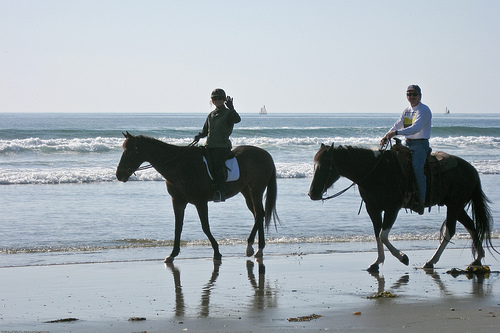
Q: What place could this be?
A: It is a beach.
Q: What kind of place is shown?
A: It is a beach.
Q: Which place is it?
A: It is a beach.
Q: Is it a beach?
A: Yes, it is a beach.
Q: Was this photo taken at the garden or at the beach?
A: It was taken at the beach.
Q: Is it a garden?
A: No, it is a beach.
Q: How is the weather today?
A: It is clear.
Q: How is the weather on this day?
A: It is clear.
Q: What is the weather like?
A: It is clear.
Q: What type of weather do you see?
A: It is clear.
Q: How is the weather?
A: It is clear.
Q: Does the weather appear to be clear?
A: Yes, it is clear.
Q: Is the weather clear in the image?
A: Yes, it is clear.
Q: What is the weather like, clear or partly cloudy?
A: It is clear.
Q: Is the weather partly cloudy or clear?
A: It is clear.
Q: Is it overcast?
A: No, it is clear.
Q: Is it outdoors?
A: Yes, it is outdoors.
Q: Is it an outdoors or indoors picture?
A: It is outdoors.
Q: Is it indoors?
A: No, it is outdoors.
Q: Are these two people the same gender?
A: No, they are both male and female.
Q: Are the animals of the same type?
A: Yes, all the animals are horses.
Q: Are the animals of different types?
A: No, all the animals are horses.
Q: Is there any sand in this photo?
A: Yes, there is sand.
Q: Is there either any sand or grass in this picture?
A: Yes, there is sand.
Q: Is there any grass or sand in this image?
A: Yes, there is sand.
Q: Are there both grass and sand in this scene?
A: No, there is sand but no grass.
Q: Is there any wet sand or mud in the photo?
A: Yes, there is wet sand.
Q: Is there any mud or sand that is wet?
A: Yes, the sand is wet.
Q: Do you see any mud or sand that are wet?
A: Yes, the sand is wet.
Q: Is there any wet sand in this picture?
A: Yes, there is wet sand.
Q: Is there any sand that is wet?
A: Yes, there is sand that is wet.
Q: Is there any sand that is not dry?
A: Yes, there is wet sand.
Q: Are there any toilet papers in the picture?
A: No, there are no toilet papers.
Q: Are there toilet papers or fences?
A: No, there are no toilet papers or fences.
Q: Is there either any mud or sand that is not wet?
A: No, there is sand but it is wet.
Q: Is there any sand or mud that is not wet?
A: No, there is sand but it is wet.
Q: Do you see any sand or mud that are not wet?
A: No, there is sand but it is wet.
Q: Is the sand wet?
A: Yes, the sand is wet.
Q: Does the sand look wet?
A: Yes, the sand is wet.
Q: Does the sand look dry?
A: No, the sand is wet.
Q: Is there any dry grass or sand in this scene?
A: No, there is sand but it is wet.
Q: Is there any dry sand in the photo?
A: No, there is sand but it is wet.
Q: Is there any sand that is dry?
A: No, there is sand but it is wet.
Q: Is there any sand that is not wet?
A: No, there is sand but it is wet.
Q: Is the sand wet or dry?
A: The sand is wet.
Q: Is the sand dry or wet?
A: The sand is wet.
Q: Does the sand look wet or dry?
A: The sand is wet.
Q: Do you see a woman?
A: Yes, there is a woman.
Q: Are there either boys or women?
A: Yes, there is a woman.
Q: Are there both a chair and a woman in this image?
A: No, there is a woman but no chairs.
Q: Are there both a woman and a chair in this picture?
A: No, there is a woman but no chairs.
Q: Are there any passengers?
A: No, there are no passengers.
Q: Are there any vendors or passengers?
A: No, there are no passengers or vendors.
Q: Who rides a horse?
A: The woman rides a horse.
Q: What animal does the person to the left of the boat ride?
A: The woman rides a horse.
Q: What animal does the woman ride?
A: The woman rides a horse.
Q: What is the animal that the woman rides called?
A: The animal is a horse.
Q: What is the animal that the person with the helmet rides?
A: The animal is a horse.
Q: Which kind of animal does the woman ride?
A: The woman rides a horse.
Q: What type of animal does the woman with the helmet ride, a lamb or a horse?
A: The woman rides a horse.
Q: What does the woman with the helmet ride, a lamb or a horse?
A: The woman rides a horse.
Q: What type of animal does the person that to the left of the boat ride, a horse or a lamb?
A: The woman rides a horse.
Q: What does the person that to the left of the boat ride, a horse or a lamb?
A: The woman rides a horse.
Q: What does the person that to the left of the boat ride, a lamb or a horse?
A: The woman rides a horse.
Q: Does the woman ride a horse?
A: Yes, the woman rides a horse.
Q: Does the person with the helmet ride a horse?
A: Yes, the woman rides a horse.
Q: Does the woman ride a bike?
A: No, the woman rides a horse.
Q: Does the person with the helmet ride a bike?
A: No, the woman rides a horse.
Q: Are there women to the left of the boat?
A: Yes, there is a woman to the left of the boat.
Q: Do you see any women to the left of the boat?
A: Yes, there is a woman to the left of the boat.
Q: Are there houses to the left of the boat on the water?
A: No, there is a woman to the left of the boat.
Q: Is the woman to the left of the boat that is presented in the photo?
A: Yes, the woman is to the left of the boat.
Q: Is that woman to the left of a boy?
A: No, the woman is to the left of the boat.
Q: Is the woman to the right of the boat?
A: No, the woman is to the left of the boat.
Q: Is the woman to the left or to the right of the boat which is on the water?
A: The woman is to the left of the boat.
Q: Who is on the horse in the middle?
A: The woman is on the horse.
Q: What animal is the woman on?
A: The woman is on the horse.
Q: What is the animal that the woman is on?
A: The animal is a horse.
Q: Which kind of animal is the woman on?
A: The woman is on the horse.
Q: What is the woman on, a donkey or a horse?
A: The woman is on a horse.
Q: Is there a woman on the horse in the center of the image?
A: Yes, there is a woman on the horse.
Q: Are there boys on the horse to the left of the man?
A: No, there is a woman on the horse.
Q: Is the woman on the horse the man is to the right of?
A: Yes, the woman is on the horse.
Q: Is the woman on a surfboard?
A: No, the woman is on the horse.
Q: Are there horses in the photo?
A: Yes, there is a horse.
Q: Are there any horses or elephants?
A: Yes, there is a horse.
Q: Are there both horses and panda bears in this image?
A: No, there is a horse but no panda bears.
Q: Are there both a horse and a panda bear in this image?
A: No, there is a horse but no panda bears.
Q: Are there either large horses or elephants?
A: Yes, there is a large horse.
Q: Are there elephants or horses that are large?
A: Yes, the horse is large.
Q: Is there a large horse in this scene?
A: Yes, there is a large horse.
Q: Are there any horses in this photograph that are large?
A: Yes, there is a horse that is large.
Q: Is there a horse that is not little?
A: Yes, there is a large horse.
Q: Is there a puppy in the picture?
A: No, there are no puppies.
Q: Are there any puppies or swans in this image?
A: No, there are no puppies or swans.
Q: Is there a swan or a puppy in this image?
A: No, there are no puppies or swans.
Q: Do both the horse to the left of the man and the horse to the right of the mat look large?
A: Yes, both the horse and the horse are large.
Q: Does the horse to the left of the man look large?
A: Yes, the horse is large.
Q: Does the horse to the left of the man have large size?
A: Yes, the horse is large.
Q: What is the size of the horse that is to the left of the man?
A: The horse is large.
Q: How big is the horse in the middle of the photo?
A: The horse is large.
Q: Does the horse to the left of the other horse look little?
A: No, the horse is large.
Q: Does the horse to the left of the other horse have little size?
A: No, the horse is large.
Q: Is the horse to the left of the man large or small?
A: The horse is large.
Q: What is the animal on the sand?
A: The animal is a horse.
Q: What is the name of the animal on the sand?
A: The animal is a horse.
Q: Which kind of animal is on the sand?
A: The animal is a horse.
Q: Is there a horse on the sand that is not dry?
A: Yes, there is a horse on the sand.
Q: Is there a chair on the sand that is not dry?
A: No, there is a horse on the sand.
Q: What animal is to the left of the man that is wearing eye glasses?
A: The animal is a horse.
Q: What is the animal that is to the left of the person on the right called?
A: The animal is a horse.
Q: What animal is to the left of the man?
A: The animal is a horse.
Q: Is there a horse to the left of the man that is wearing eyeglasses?
A: Yes, there is a horse to the left of the man.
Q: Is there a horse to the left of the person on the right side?
A: Yes, there is a horse to the left of the man.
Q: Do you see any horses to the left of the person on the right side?
A: Yes, there is a horse to the left of the man.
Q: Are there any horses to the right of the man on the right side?
A: No, the horse is to the left of the man.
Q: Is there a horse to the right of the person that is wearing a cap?
A: No, the horse is to the left of the man.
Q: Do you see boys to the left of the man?
A: No, there is a horse to the left of the man.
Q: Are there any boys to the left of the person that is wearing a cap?
A: No, there is a horse to the left of the man.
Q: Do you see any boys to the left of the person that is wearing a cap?
A: No, there is a horse to the left of the man.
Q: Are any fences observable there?
A: No, there are no fences.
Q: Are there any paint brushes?
A: No, there are no paint brushes.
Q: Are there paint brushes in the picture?
A: No, there are no paint brushes.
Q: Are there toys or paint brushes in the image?
A: No, there are no paint brushes or toys.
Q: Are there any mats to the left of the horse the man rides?
A: Yes, there is a mat to the left of the horse.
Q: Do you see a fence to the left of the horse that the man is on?
A: No, there is a mat to the left of the horse.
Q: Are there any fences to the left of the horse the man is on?
A: No, there is a mat to the left of the horse.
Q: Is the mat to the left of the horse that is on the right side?
A: Yes, the mat is to the left of the horse.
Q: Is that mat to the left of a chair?
A: No, the mat is to the left of the horse.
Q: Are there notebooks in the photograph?
A: No, there are no notebooks.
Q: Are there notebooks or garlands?
A: No, there are no notebooks or garlands.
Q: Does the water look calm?
A: Yes, the water is calm.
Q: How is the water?
A: The water is calm.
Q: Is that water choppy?
A: No, the water is calm.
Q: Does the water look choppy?
A: No, the water is calm.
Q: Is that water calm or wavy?
A: The water is calm.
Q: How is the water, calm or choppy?
A: The water is calm.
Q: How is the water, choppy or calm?
A: The water is calm.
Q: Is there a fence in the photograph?
A: No, there are no fences.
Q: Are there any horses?
A: Yes, there is a horse.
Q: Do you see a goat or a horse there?
A: Yes, there is a horse.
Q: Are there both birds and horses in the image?
A: No, there is a horse but no birds.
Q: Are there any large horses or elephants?
A: Yes, there is a large horse.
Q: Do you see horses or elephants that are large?
A: Yes, the horse is large.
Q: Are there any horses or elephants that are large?
A: Yes, the horse is large.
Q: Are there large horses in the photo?
A: Yes, there is a large horse.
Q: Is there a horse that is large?
A: Yes, there is a horse that is large.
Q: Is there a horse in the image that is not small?
A: Yes, there is a large horse.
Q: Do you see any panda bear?
A: No, there are no panda bears.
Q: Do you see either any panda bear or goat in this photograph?
A: No, there are no panda bears or goats.